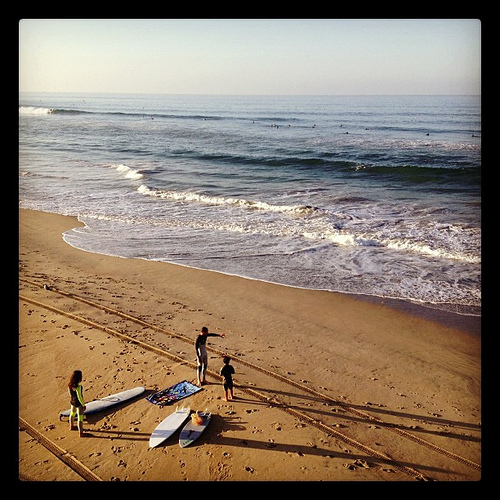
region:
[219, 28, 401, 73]
A blue color sky with clouds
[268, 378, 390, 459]
Shadow of the peoples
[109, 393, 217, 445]
Surfboard kept in the wetsand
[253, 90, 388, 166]
Blue color sea water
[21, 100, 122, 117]
Waves in the sea water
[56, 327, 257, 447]
three persons are standing near the surf board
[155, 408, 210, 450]
white color surf board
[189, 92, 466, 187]
waves in the sea water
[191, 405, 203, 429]
things kept in the surfboard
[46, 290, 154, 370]
sand with foot steps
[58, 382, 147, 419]
a white surfboard in the sand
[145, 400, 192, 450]
a white surfboard in the sand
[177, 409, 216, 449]
a white surfboard in the sand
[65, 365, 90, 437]
a surfer in a yellow wetsuit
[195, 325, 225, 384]
a surfer in a white and black wetsuit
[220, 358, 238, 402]
a young surfer being taught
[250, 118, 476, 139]
birds in the calm ocean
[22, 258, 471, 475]
footprints in the sand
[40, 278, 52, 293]
a lone bird in the sand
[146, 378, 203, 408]
a beach towel in the sand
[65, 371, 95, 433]
a little girl wearing surfing clothes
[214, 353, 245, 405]
a little boy wearing surfing clothes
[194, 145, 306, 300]
the coast of the ocean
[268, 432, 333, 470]
footprints in the beaches sand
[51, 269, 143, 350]
tire tracks in the sand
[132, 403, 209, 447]
two white surf boards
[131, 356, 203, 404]
a towel laid out in the sand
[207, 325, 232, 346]
a mans arm pointing in the distance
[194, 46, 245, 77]
a crisp blue sky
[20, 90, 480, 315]
the large body of water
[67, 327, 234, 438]
the people at the beach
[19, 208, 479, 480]
the marks in the sand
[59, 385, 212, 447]
the surfboards on the sand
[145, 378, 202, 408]
the towel on the sand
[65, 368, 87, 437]
the person standing next to the surfboard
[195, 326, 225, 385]
the person standing next to the towel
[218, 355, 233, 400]
the person standing near the two surfboards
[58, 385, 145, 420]
the longest surfboard on the sand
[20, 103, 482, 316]
the white waters in the ocean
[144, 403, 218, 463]
the surfboards on the beach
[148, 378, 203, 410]
the beach towel on the beach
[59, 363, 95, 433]
the women in the wetsuit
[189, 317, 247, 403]
the man talking to the child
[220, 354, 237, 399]
the child on the beach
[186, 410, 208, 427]
the item on the surfboard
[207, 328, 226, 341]
the mans hand out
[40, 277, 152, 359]
the tire lines in the sand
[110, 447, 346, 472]
the prints in the sand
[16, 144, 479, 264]
the tide coming into the shore